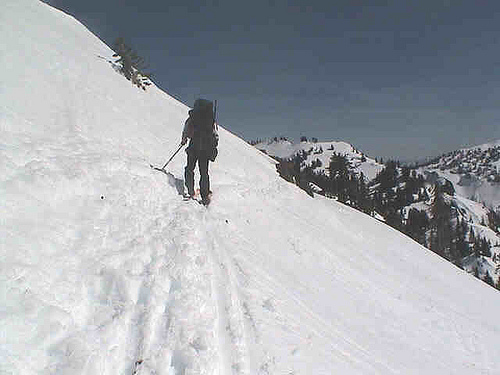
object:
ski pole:
[162, 143, 186, 170]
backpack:
[190, 98, 215, 160]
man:
[179, 109, 220, 206]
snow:
[0, 0, 500, 375]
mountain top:
[251, 136, 500, 292]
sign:
[276, 119, 378, 190]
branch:
[112, 36, 153, 91]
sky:
[36, 0, 500, 83]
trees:
[246, 136, 499, 291]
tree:
[111, 36, 153, 90]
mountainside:
[0, 0, 499, 375]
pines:
[274, 148, 493, 259]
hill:
[0, 0, 500, 375]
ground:
[0, 0, 497, 375]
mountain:
[0, 0, 500, 375]